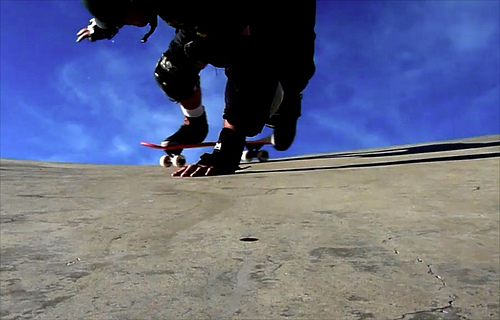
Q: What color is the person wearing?
A: Black.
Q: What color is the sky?
A: Blue.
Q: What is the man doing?
A: Skateboarding.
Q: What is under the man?
A: Ground.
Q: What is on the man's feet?
A: They are bare.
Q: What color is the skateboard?
A: Red.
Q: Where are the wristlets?
A: On the man's hand.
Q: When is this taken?
A: During the daytime.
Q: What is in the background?
A: Blue sky.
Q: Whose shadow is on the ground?
A: Skateboarder.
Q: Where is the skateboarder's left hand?
A: On the ground.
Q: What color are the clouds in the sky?
A: White.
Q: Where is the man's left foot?
A: Off the ground.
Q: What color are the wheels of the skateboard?
A: White.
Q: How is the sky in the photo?
A: Bright blue.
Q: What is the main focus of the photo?
A: Skateboarder on a skateboard.